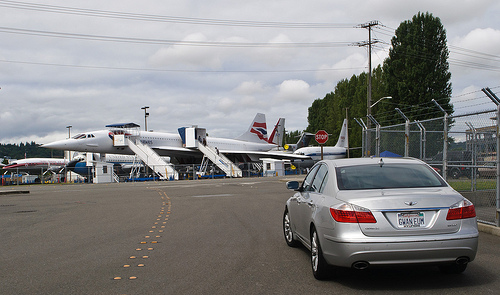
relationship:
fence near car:
[365, 111, 497, 225] [281, 155, 481, 280]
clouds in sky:
[11, 36, 305, 132] [6, 2, 498, 144]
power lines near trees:
[1, 1, 360, 70] [306, 14, 447, 167]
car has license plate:
[281, 155, 481, 280] [394, 213, 431, 231]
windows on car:
[301, 167, 329, 193] [281, 155, 481, 280]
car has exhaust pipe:
[281, 155, 481, 280] [352, 261, 370, 273]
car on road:
[281, 155, 481, 280] [8, 180, 279, 288]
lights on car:
[333, 206, 477, 224] [281, 155, 481, 280]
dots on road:
[113, 187, 172, 277] [8, 180, 279, 288]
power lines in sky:
[1, 1, 360, 70] [6, 2, 498, 144]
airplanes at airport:
[8, 120, 283, 179] [3, 102, 495, 185]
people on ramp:
[195, 136, 235, 176] [198, 143, 241, 176]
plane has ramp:
[6, 158, 67, 177] [124, 138, 180, 181]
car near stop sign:
[281, 155, 481, 280] [315, 129, 329, 143]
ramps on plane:
[129, 137, 240, 181] [53, 112, 284, 181]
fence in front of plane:
[13, 161, 307, 184] [6, 158, 67, 177]